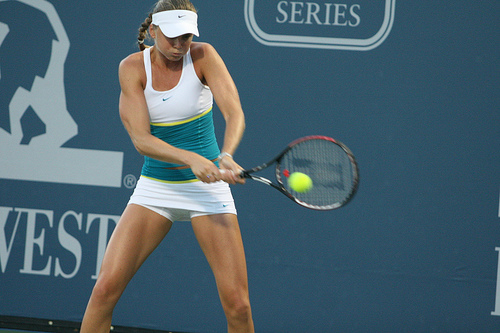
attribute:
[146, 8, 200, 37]
visor — white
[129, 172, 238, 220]
skirt — white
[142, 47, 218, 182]
tank top — Nike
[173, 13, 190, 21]
swoosh — black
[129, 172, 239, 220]
shorts — white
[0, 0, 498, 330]
wall — blue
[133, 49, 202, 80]
visor — white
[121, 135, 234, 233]
outfit — white and blue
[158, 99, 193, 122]
visor — white 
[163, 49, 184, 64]
visor — white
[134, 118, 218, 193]
mid section — blue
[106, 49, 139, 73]
pony tail — blond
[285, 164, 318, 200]
tennis ball — yellowish, green, yellow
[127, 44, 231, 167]
white tank top — green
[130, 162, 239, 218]
white skirt — green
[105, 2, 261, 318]
woman playing — blond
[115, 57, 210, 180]
woman's arm — muscular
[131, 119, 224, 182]
middle of shirt — turquoise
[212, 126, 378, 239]
racket — black and red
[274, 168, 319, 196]
ball — yellow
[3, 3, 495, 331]
background — blue